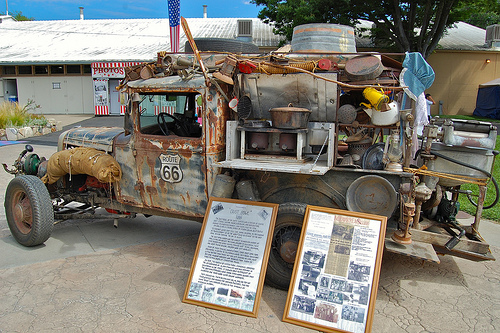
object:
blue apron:
[397, 50, 434, 146]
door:
[135, 86, 210, 225]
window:
[123, 81, 205, 141]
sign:
[89, 61, 145, 80]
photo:
[345, 257, 374, 284]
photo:
[299, 247, 325, 272]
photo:
[313, 299, 338, 323]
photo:
[290, 293, 315, 318]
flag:
[165, 2, 179, 53]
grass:
[439, 112, 500, 222]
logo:
[157, 151, 183, 183]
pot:
[267, 101, 311, 130]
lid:
[268, 102, 311, 113]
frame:
[178, 199, 280, 317]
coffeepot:
[361, 85, 391, 113]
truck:
[5, 45, 498, 293]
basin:
[289, 21, 356, 60]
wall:
[430, 54, 496, 119]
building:
[393, 27, 499, 121]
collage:
[281, 201, 387, 333]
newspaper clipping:
[323, 214, 357, 280]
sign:
[280, 203, 388, 333]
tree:
[250, 0, 499, 60]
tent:
[469, 82, 499, 120]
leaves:
[251, 0, 493, 48]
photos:
[93, 60, 145, 77]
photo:
[319, 276, 330, 287]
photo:
[313, 276, 345, 306]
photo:
[349, 258, 371, 280]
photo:
[303, 248, 323, 269]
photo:
[342, 304, 365, 323]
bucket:
[343, 176, 404, 220]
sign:
[182, 196, 277, 318]